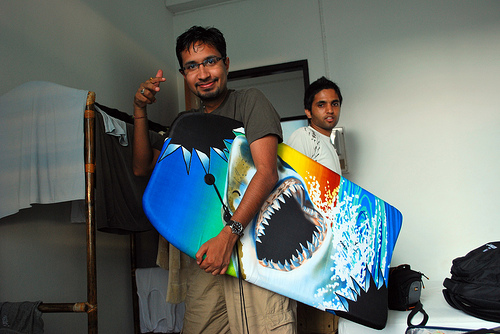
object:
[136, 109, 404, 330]
board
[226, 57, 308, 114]
doorway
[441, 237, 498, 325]
black bagpack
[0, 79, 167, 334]
wooden bed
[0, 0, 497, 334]
bedroom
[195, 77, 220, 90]
moustache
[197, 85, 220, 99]
beard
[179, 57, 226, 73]
glasses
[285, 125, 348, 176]
shirt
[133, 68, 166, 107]
hand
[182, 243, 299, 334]
pants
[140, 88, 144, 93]
ring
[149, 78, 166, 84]
finger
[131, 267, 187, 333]
shirt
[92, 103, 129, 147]
shirt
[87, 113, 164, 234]
shirt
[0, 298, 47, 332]
shirt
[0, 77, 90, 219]
shirt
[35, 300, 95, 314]
rail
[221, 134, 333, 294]
shark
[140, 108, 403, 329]
surf board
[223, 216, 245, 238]
watch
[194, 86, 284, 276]
arm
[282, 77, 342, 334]
man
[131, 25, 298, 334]
man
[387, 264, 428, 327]
luggage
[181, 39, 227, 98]
face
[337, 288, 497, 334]
bed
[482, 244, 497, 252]
lettering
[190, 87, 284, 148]
shirt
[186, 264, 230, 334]
khaki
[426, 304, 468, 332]
table